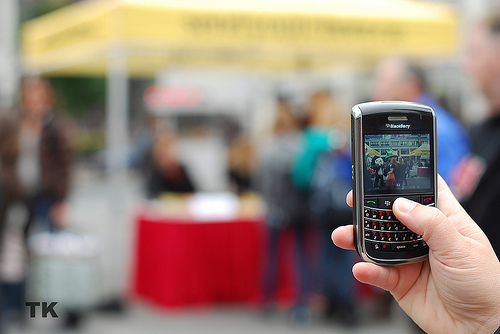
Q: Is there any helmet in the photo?
A: No, there are no helmets.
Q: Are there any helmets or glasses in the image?
A: No, there are no helmets or glasses.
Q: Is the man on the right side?
A: Yes, the man is on the right of the image.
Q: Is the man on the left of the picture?
A: No, the man is on the right of the image.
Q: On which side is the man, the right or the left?
A: The man is on the right of the image.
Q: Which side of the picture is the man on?
A: The man is on the right of the image.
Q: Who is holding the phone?
A: The man is holding the phone.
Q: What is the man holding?
A: The man is holding the telephone.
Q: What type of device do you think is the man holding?
A: The man is holding the telephone.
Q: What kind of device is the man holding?
A: The man is holding the telephone.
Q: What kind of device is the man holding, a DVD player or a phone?
A: The man is holding a phone.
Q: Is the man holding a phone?
A: Yes, the man is holding a phone.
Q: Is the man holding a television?
A: No, the man is holding a phone.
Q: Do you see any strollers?
A: No, there are no strollers.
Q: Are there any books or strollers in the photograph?
A: No, there are no strollers or books.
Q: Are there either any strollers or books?
A: No, there are no strollers or books.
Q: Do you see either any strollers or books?
A: No, there are no strollers or books.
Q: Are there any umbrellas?
A: No, there are no umbrellas.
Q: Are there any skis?
A: No, there are no skis.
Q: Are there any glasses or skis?
A: No, there are no skis or glasses.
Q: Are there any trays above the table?
A: No, there is a tent above the table.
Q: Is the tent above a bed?
A: No, the tent is above the table.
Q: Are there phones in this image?
A: Yes, there is a phone.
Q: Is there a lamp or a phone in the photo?
A: Yes, there is a phone.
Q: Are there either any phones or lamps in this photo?
A: Yes, there is a phone.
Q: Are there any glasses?
A: No, there are no glasses.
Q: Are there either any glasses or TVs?
A: No, there are no glasses or tvs.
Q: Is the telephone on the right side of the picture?
A: Yes, the telephone is on the right of the image.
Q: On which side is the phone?
A: The phone is on the right of the image.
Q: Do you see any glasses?
A: No, there are no glasses.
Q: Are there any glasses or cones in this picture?
A: No, there are no glasses or cones.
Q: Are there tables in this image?
A: Yes, there is a table.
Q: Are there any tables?
A: Yes, there is a table.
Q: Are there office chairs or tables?
A: Yes, there is a table.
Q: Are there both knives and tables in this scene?
A: No, there is a table but no knives.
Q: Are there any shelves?
A: No, there are no shelves.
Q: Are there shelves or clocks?
A: No, there are no shelves or clocks.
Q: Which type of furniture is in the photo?
A: The furniture is a table.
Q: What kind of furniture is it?
A: The piece of furniture is a table.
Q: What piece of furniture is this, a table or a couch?
A: This is a table.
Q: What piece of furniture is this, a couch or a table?
A: This is a table.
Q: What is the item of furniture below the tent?
A: The piece of furniture is a table.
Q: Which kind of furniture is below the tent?
A: The piece of furniture is a table.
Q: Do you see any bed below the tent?
A: No, there is a table below the tent.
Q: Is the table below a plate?
A: No, the table is below the tent.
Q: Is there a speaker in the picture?
A: No, there are no speakers.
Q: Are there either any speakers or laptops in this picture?
A: No, there are no speakers or laptops.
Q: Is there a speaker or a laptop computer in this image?
A: No, there are no speakers or laptops.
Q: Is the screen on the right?
A: Yes, the screen is on the right of the image.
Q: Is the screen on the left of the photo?
A: No, the screen is on the right of the image.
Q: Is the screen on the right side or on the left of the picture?
A: The screen is on the right of the image.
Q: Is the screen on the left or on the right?
A: The screen is on the right of the image.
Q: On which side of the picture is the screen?
A: The screen is on the right of the image.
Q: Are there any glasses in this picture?
A: No, there are no glasses.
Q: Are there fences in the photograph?
A: No, there are no fences.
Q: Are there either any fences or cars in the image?
A: No, there are no fences or cars.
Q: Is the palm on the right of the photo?
A: Yes, the palm is on the right of the image.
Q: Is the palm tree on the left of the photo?
A: No, the palm tree is on the right of the image.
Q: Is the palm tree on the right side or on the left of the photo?
A: The palm tree is on the right of the image.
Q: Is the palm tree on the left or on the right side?
A: The palm tree is on the right of the image.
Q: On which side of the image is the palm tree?
A: The palm tree is on the right of the image.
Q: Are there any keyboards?
A: Yes, there is a keyboard.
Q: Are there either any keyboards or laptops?
A: Yes, there is a keyboard.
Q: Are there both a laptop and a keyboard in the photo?
A: No, there is a keyboard but no laptops.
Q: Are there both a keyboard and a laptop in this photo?
A: No, there is a keyboard but no laptops.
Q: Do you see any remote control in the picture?
A: No, there are no remote controls.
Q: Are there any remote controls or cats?
A: No, there are no remote controls or cats.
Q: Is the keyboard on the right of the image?
A: Yes, the keyboard is on the right of the image.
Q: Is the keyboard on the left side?
A: No, the keyboard is on the right of the image.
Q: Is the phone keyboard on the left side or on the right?
A: The keyboard is on the right of the image.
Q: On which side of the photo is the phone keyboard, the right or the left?
A: The keyboard is on the right of the image.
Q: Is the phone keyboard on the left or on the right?
A: The keyboard is on the right of the image.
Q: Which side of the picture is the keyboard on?
A: The keyboard is on the right of the image.